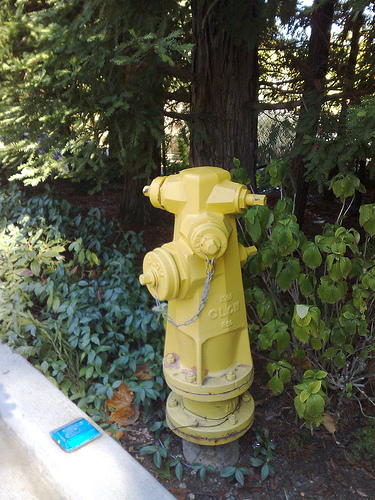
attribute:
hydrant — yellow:
[137, 154, 271, 454]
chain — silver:
[143, 255, 216, 333]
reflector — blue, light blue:
[46, 412, 101, 459]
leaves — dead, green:
[4, 194, 287, 492]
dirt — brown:
[111, 320, 373, 500]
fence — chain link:
[152, 103, 306, 209]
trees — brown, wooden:
[176, 1, 284, 222]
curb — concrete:
[2, 340, 182, 499]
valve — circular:
[203, 238, 222, 259]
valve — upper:
[244, 192, 269, 213]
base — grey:
[174, 436, 245, 479]